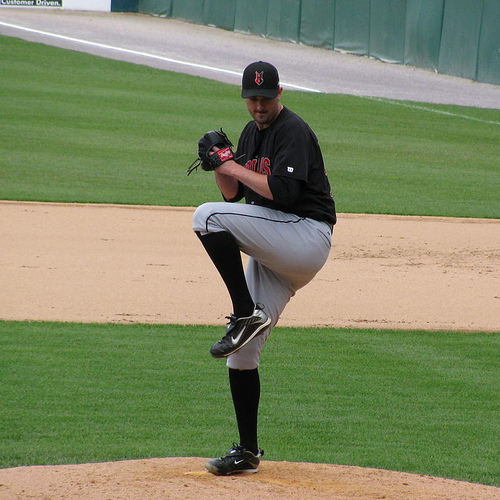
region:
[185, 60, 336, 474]
pitcher standing on one leg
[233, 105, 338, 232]
pitcher is wearing black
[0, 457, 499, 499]
pitcher is on mound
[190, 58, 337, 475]
pitcher will throw ball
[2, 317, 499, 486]
grass is very green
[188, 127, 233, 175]
pitcher has ball in glove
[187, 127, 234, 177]
glove on hand is black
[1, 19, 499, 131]
white stripe behind pitcher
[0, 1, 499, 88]
wall behind the pitcher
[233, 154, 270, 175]
logo on pitchers shirt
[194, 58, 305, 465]
pitcher winds up to throw baseball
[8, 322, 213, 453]
green grass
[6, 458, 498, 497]
the pitcher's mound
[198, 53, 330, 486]
baseball player standing on right leg with knees raised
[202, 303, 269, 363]
black and white baseball cleat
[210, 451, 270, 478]
black and white baseball cleat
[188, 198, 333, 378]
grey pants with a black stripe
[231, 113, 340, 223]
black and red baseball jerey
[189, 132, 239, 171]
black and red baseball glove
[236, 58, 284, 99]
black and red baseball hat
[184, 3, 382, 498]
Baseball player starting to pitch the ball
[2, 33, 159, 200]
The ground is covere with green grass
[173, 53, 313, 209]
Player is holding the ball in his hand.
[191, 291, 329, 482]
the logo indicates nike brand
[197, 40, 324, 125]
Player is wearing a black hat.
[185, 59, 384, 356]
Player holding his leg up near his hands.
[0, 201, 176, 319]
it is a brown dusty ground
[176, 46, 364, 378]
player is wearing a black shirt.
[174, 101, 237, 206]
the baseball player has black gloves.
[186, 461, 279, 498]
the player is standing on a mark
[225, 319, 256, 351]
Nike logo on side of shoe.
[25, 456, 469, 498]
Pitcher's mound in a baseball dimond.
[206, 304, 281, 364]
Black tennis shoe.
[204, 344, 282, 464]
Black baseball athletic sock.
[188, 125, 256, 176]
A hand wearing a black baseball glove.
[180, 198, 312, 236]
A black stripe running down the baseball uniform pants.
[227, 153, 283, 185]
Team name on baseball jersey.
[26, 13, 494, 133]
White line showing the inside of a baseball diamond.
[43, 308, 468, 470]
Green turf in a baseball diamond.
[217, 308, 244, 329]
Black shoe laces.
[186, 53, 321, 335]
Baseball Pitcher winds up throw.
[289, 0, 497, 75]
Spectator bleachers back wall.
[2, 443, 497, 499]
Pitcher's mound tan sand.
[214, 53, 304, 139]
Baseball cap on head.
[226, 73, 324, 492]
Black, gray and red uniform.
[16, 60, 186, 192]
Green grass recently mowed.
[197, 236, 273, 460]
Both socks are black.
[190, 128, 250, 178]
Baseball hidden by hands.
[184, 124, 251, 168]
Baseball glove important tool.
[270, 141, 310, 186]
Arm small white emblem.